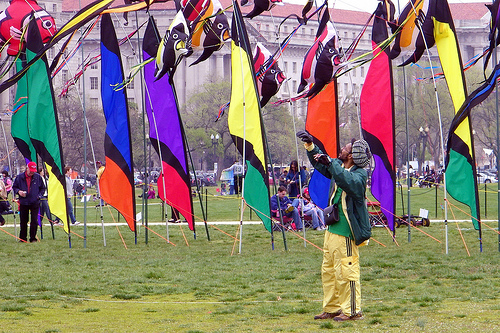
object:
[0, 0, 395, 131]
building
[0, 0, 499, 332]
event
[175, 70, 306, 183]
tree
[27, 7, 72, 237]
flag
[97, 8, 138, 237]
flag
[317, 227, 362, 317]
pants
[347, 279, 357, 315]
stripes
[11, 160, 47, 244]
man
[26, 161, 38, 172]
baseball cap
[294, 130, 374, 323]
man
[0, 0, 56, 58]
clownfish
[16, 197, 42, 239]
jeans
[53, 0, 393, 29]
roof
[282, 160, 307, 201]
woman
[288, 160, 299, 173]
head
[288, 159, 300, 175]
dark hair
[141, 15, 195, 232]
flag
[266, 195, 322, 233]
bench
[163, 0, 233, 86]
kite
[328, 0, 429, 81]
kite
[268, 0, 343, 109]
kite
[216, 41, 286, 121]
kite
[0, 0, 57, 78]
kite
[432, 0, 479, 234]
flag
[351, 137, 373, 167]
hat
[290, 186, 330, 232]
woman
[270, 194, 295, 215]
coat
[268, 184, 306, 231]
person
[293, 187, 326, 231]
person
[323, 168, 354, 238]
shirt